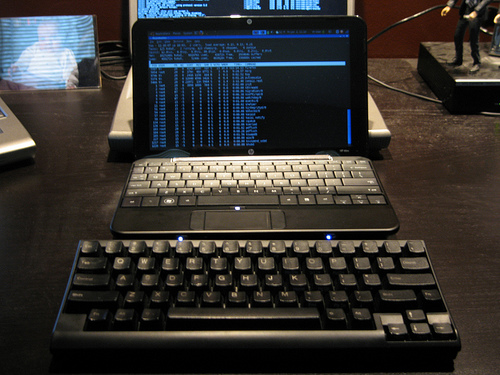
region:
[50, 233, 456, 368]
a full size black computer keyboard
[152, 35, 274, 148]
black writing on the screen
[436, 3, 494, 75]
an action figure on a pedestal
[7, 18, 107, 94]
a photo of a baby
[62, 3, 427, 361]
two laptops and a keyboard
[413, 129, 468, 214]
a dark brown wooden table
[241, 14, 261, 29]
built in camera on the laptop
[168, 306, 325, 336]
black space bar on the keyboard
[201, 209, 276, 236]
the built in mouse on the laptop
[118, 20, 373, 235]
this is a laptop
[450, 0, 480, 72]
this is a statue man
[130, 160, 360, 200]
this is a keyboard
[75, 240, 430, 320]
the buttons are many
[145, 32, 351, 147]
this is the screen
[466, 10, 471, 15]
the man is light skinned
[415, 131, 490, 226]
this is a table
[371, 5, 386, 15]
this is a wall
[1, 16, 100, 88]
this is a television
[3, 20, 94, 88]
the television is on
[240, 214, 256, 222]
part of a mouse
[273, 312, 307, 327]
part of the backspace button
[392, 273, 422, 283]
part of the enter button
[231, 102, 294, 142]
monitor of a laptop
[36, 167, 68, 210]
part of a table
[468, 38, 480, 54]
left leg of a toy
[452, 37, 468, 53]
right leg of the toy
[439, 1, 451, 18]
right hand of the toy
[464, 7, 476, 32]
left hand of the toy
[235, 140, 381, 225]
part of a keyboard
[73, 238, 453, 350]
The detached black keyboard.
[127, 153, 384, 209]
The keyboard on the laptop.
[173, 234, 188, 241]
The small left blue light on the laptop.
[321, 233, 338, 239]
The small right blue light on the laptop.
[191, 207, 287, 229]
The mouse pad on the laptop.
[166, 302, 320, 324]
The space bar on the detached keyboard.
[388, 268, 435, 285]
The enter key on the detached keyboard.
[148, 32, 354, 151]
The screen of the laptop behind the detached keyboard.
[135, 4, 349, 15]
The top of the screen of the laptop behind the main laptop in the photo.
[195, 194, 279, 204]
The space bar on the keyboard of the laptop.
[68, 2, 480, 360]
computers sitting on desktop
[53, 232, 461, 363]
keyboard on desktop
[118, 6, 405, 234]
laptop sitting behind keyboard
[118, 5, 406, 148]
laptop behind laptop and keyboard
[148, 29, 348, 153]
blue lighted display on screen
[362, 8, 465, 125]
cables attached to laptop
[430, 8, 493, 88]
legs of a figurine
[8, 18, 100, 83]
photograph sitting on desk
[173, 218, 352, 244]
indicator lights on laptop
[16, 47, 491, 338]
solid black desktop